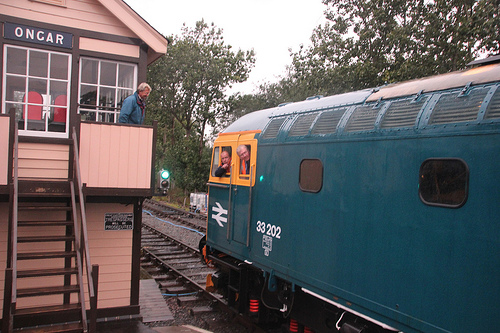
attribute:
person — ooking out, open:
[232, 141, 256, 180]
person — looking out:
[211, 145, 233, 184]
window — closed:
[412, 151, 474, 216]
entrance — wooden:
[2, 98, 93, 327]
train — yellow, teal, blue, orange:
[195, 46, 500, 327]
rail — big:
[147, 201, 222, 329]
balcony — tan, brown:
[78, 114, 161, 204]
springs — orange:
[241, 293, 310, 332]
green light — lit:
[158, 166, 170, 181]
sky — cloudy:
[139, 0, 315, 20]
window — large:
[3, 48, 80, 139]